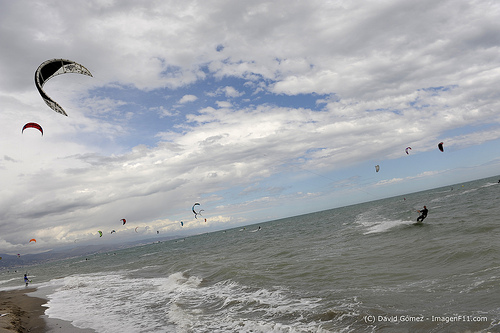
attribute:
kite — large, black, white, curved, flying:
[32, 56, 92, 117]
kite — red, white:
[13, 113, 51, 147]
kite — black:
[17, 44, 99, 117]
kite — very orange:
[28, 235, 38, 247]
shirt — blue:
[23, 273, 27, 279]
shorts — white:
[23, 280, 28, 283]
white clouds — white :
[58, 5, 459, 97]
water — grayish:
[236, 259, 435, 307]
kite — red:
[15, 118, 49, 148]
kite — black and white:
[23, 56, 109, 139]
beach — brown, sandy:
[1, 286, 48, 332]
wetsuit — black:
[417, 204, 432, 223]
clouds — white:
[2, 3, 491, 245]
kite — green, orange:
[89, 223, 103, 241]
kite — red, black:
[18, 117, 49, 138]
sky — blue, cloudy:
[4, 0, 495, 270]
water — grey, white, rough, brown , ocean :
[0, 177, 498, 330]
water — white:
[3, 262, 356, 330]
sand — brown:
[3, 281, 101, 330]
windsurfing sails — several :
[90, 192, 230, 246]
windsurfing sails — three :
[365, 133, 450, 176]